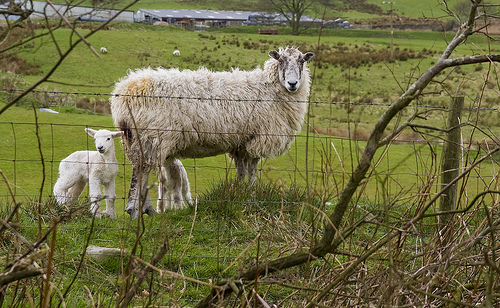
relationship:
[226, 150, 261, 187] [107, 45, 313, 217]
front legs of sheep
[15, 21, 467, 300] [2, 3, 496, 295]
field of grass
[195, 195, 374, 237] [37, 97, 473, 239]
grass by fence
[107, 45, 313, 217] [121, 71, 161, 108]
sheep has dirty wool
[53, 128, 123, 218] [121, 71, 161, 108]
baby sheep has dirty wool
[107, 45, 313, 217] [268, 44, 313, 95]
sheep has head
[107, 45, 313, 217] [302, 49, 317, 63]
sheep has ear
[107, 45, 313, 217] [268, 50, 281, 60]
sheep has ear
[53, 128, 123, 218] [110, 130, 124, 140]
baby sheep has ear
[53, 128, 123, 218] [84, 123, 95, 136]
baby sheep has ear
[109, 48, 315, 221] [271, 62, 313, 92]
sheep has mouth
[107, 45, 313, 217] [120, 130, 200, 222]
sheep has legs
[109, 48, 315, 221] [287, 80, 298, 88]
sheep has nose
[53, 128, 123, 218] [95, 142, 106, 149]
baby sheep has sheep's nose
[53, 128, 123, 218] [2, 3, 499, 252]
baby sheep in field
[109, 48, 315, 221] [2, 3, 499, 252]
sheep in field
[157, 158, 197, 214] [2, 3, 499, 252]
lamb in field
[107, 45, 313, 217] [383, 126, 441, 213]
sheep behind fence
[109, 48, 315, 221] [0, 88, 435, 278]
sheep behind fence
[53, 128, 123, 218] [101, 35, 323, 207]
baby sheep nursing sheep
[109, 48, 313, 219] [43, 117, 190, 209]
mother of lambs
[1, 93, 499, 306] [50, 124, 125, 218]
fencing in front of lamb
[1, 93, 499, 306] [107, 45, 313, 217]
fencing in front of sheep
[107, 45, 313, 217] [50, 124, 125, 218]
sheep with lamb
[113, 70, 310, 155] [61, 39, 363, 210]
body of sheep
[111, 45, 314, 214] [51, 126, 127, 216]
mother and baby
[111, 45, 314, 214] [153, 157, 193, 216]
mother and baby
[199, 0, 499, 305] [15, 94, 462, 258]
stick behind fence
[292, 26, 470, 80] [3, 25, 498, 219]
bushes in field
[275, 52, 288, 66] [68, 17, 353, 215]
eye of sheep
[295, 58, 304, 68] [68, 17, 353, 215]
eye of sheep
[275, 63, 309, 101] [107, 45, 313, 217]
nose of sheep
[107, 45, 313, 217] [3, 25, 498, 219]
sheep standing in field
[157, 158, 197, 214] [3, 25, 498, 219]
lamb standing in field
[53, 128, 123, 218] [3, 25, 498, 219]
baby sheep standing in field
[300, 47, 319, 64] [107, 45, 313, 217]
ear of sheep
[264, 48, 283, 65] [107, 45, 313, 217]
ear of sheep